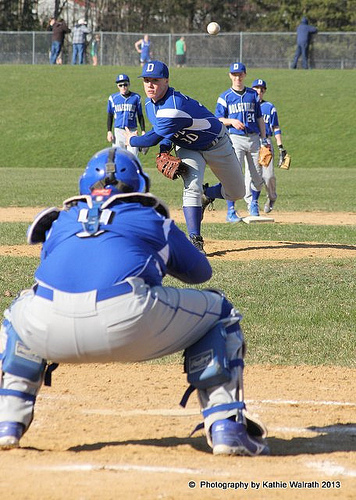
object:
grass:
[0, 64, 356, 212]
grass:
[0, 220, 356, 246]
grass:
[0, 255, 356, 370]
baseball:
[207, 21, 221, 34]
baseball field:
[0, 61, 356, 500]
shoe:
[211, 418, 270, 457]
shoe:
[0, 421, 26, 450]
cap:
[230, 62, 246, 74]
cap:
[115, 73, 129, 82]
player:
[106, 73, 149, 158]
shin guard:
[179, 287, 247, 439]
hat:
[137, 60, 169, 80]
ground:
[291, 97, 336, 134]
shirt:
[175, 39, 185, 56]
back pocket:
[106, 311, 151, 361]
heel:
[211, 418, 247, 456]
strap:
[41, 225, 168, 278]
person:
[135, 35, 154, 67]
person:
[90, 34, 101, 66]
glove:
[155, 152, 186, 181]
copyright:
[187, 480, 341, 490]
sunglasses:
[119, 83, 128, 87]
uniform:
[129, 86, 247, 208]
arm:
[132, 108, 175, 147]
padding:
[27, 205, 62, 245]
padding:
[62, 192, 169, 220]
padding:
[76, 207, 113, 238]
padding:
[178, 312, 245, 410]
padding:
[0, 318, 44, 384]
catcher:
[0, 146, 271, 458]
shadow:
[144, 77, 173, 106]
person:
[290, 17, 318, 69]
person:
[175, 36, 187, 68]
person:
[118, 60, 247, 257]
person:
[71, 18, 92, 65]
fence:
[0, 31, 356, 71]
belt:
[33, 277, 153, 302]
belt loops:
[31, 276, 147, 318]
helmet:
[78, 146, 150, 198]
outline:
[242, 397, 356, 476]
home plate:
[82, 407, 202, 418]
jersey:
[34, 201, 213, 295]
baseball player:
[214, 62, 273, 224]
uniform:
[215, 85, 263, 191]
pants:
[0, 277, 247, 450]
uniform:
[106, 90, 145, 156]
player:
[243, 78, 291, 214]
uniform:
[243, 100, 279, 211]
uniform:
[0, 200, 248, 447]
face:
[143, 77, 165, 99]